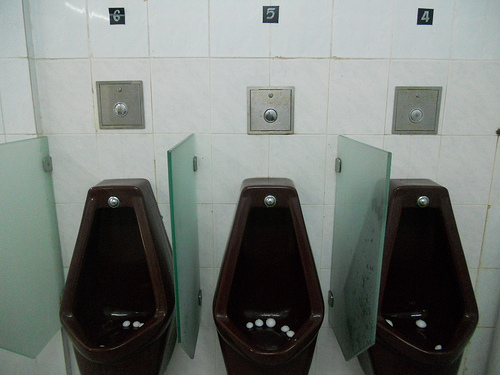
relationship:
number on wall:
[421, 10, 431, 23] [0, 1, 498, 369]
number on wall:
[267, 8, 275, 19] [26, 2, 496, 326]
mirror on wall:
[7, 13, 30, 127] [5, 2, 488, 131]